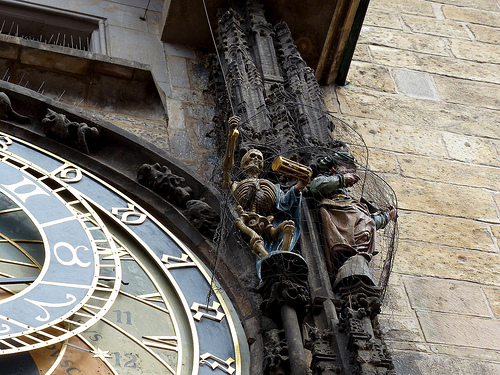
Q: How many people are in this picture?
A: None.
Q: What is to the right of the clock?
A: Two statues.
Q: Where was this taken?
A: Under a clock.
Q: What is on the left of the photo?
A: A clock.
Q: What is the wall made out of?
A: Brick.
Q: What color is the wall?
A: Tan.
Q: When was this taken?
A: During the day.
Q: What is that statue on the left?
A: A skeleton.